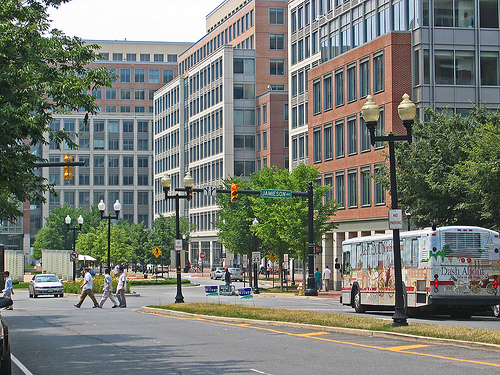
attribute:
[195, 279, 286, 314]
signs grass — blue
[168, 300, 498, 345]
medians — of street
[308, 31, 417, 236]
panel — brick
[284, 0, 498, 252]
building — gray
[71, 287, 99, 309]
pants — beige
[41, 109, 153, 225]
windows — lit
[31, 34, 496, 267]
buildings — geometric, office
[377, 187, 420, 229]
sign — white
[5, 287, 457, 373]
street — paved 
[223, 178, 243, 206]
light — red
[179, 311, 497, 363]
stripes — yellow, white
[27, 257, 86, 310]
car — white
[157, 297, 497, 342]
island — grassy